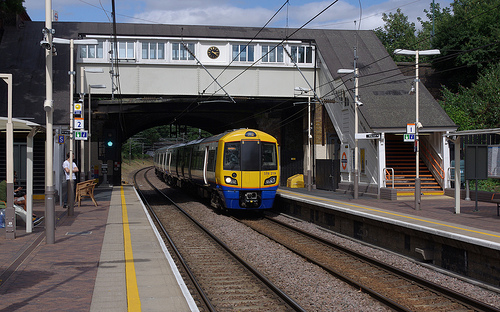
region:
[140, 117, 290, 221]
Train is arriving to train station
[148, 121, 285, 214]
Train is yellow and blue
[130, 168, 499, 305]
Two train rails on train station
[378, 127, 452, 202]
Stairs are on the left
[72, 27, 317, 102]
Bridge over the rails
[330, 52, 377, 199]
Electric pole facing railroad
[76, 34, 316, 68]
Bridge has windows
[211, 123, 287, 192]
The front of train is yellow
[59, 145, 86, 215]
Person is standing with the arms crossed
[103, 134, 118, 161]
The traffic light is in green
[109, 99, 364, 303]
a train in a train station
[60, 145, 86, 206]
a man standing beside the train tracks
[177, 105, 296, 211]
a yellow and blue train at a station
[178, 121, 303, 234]
a train on tracks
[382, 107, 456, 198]
orange stairs at a train station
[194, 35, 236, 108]
a clock at a train station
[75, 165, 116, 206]
chairs sitting beside train tracks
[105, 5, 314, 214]
a train going throw a tunnel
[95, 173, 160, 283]
a yellow line next to train tracks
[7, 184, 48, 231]
man sitting at train station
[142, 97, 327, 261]
This is a train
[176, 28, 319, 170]
A clock tells time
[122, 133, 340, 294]
Two tracks are used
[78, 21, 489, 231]
The building has two stories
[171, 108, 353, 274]
The train is yellow and blue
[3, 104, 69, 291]
This is a waiting area for travellers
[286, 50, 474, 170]
Lights are used in the evening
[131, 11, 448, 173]
There are clouds in the sky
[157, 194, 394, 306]
Gravel is next to the tracks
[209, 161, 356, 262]
The train has 2 lights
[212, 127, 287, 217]
a blue and yellow train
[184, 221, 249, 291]
train tracks and railroad ties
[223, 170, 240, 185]
a headlight on a train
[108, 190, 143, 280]
yellow line painted on a train loading platform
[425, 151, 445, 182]
a metal railing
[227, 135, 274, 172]
windshield on a train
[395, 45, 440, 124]
streetlights on a pole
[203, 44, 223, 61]
a clock on a building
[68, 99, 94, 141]
signs on a pole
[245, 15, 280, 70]
power lines for a train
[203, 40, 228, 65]
A black clock face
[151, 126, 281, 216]
A yellow and blue colored train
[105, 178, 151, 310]
A yellow painted line on the train platform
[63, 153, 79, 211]
A man standing near the train sign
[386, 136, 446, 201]
Orange stairs on the right side of the platform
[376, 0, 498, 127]
Trees with green leaves on the right side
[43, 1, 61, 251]
A tall silver and gray pole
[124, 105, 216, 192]
An arched opening of the train station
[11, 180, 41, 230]
A person sitting down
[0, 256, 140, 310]
Shadows on the platform